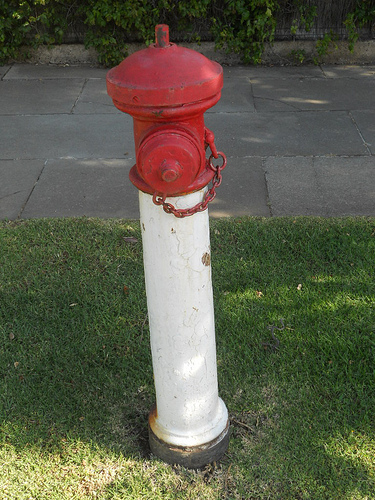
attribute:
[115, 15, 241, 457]
hydrant — red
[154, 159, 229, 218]
chain — red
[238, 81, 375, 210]
cement — gray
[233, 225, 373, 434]
grass — green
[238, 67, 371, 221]
sidewalk — gray, concrete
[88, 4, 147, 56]
plants — green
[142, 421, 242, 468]
base — dark, concrete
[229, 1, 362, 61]
leaves — green, growing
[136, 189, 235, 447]
pole — white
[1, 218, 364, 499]
ground — green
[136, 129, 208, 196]
nob — red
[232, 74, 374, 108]
shadow — light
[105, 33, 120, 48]
leaf — green